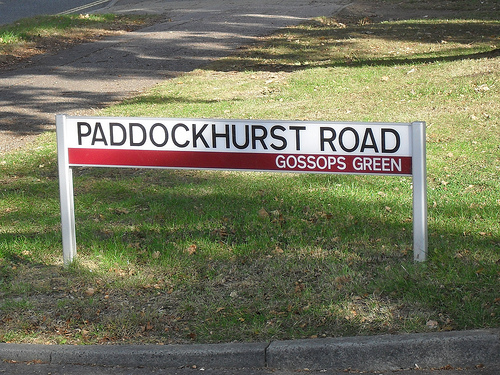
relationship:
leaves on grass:
[133, 317, 167, 336] [4, 4, 491, 342]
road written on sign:
[317, 124, 403, 154] [52, 106, 431, 266]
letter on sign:
[76, 120, 91, 145] [52, 106, 431, 266]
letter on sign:
[89, 119, 106, 149] [52, 106, 431, 266]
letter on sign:
[104, 122, 127, 147] [52, 106, 431, 266]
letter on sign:
[127, 122, 147, 148] [52, 106, 431, 266]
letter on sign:
[147, 123, 169, 147] [52, 106, 431, 266]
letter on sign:
[169, 122, 191, 146] [52, 106, 431, 266]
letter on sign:
[191, 125, 211, 150] [52, 106, 431, 266]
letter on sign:
[210, 123, 232, 147] [52, 106, 431, 266]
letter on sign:
[231, 124, 251, 149] [52, 106, 431, 266]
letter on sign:
[252, 127, 270, 154] [52, 106, 431, 266]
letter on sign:
[271, 125, 287, 150] [52, 106, 431, 266]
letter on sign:
[271, 124, 288, 156] [52, 106, 431, 266]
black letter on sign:
[288, 125, 308, 150] [52, 106, 431, 266]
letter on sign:
[316, 129, 336, 151] [52, 106, 431, 266]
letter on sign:
[339, 126, 360, 153] [52, 106, 431, 266]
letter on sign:
[360, 125, 377, 155] [52, 106, 431, 266]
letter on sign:
[380, 130, 399, 153] [52, 106, 431, 266]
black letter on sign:
[250, 122, 267, 152] [53, 114, 430, 187]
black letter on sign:
[285, 125, 309, 150] [54, 112, 421, 179]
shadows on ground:
[45, 11, 301, 76] [19, 17, 496, 117]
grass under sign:
[4, 4, 491, 342] [52, 106, 431, 266]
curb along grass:
[1, 329, 499, 373] [4, 4, 491, 342]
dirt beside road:
[337, 0, 391, 21] [3, 7, 366, 179]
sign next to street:
[65, 114, 414, 177] [0, 325, 499, 373]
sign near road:
[53, 107, 433, 182] [3, 7, 366, 179]